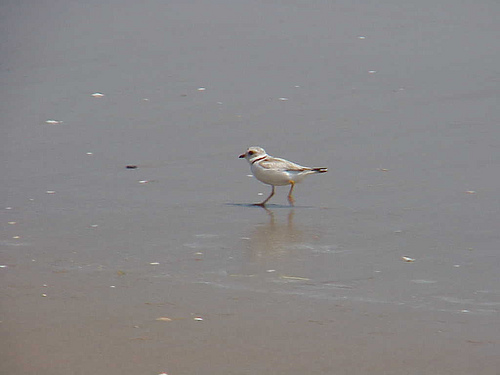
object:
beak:
[238, 154, 246, 158]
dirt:
[315, 318, 492, 372]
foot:
[253, 202, 265, 205]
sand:
[0, 309, 90, 374]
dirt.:
[20, 195, 124, 288]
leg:
[288, 180, 295, 198]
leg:
[262, 185, 274, 204]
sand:
[237, 226, 284, 247]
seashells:
[126, 292, 217, 332]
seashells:
[91, 92, 103, 97]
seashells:
[8, 220, 18, 226]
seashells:
[403, 256, 416, 263]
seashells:
[181, 66, 300, 108]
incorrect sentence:
[357, 68, 457, 145]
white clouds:
[226, 17, 276, 52]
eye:
[248, 151, 253, 155]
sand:
[343, 300, 455, 373]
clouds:
[34, 20, 228, 91]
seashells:
[45, 119, 63, 124]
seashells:
[89, 85, 106, 102]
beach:
[4, 0, 498, 372]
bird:
[238, 146, 328, 206]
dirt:
[232, 202, 307, 231]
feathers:
[260, 166, 299, 173]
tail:
[288, 166, 328, 175]